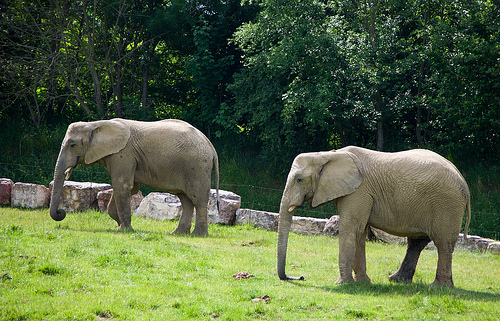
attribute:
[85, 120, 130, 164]
ear — large, grey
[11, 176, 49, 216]
stone — gray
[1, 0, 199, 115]
tree — leafless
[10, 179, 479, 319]
grass — patch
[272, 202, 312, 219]
tusk — small, white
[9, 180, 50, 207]
rocks — large, grey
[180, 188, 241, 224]
rocks — large, grey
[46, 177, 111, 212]
rocks — large, grey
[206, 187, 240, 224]
rocks — large, grey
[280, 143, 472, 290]
elephants — pictured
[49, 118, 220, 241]
elephants — pictured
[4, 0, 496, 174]
trees — very green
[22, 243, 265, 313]
grass — very green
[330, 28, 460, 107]
leaves — green